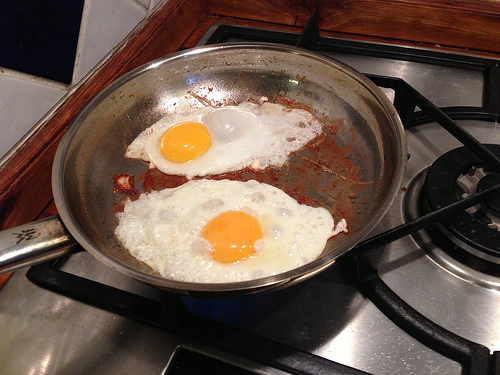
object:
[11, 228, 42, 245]
markings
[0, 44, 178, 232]
border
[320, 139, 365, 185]
marks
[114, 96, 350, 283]
eggs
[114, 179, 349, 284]
egg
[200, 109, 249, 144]
bubble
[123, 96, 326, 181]
egg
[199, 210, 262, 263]
egg yolks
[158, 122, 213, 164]
egg yolks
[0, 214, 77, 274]
handle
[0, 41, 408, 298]
frying pan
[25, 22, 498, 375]
gas stove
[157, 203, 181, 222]
bubble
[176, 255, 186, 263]
bubble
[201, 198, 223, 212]
bubble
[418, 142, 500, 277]
burner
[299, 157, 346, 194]
grease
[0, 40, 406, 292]
pan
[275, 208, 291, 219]
bubbles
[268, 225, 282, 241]
bubbles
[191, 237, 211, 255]
bubbles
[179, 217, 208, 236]
bubbles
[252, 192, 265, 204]
bubbles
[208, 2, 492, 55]
border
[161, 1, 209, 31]
boards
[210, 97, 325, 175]
egg whites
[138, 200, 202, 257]
egg whites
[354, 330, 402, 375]
grate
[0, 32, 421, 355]
pan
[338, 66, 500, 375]
surface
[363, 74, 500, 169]
unit